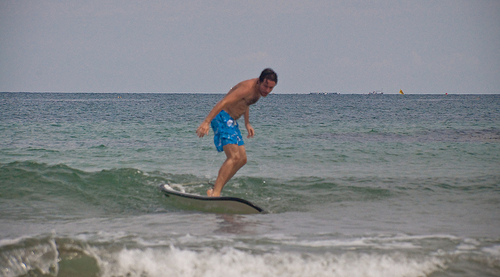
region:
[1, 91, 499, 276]
Blue ocean.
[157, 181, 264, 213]
Surfboard.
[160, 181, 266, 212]
White surfboard with black edging.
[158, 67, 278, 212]
Man on a surfboard.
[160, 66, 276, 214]
A surfer dude wearing blue shorts.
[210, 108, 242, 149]
Blue shorts with a floral print.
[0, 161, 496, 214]
An smooth ocean wave.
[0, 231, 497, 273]
Foamy ocean surf.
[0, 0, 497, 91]
A clear blue sky.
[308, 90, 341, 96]
A ship in the far distance.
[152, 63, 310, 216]
A man rides a surfboard.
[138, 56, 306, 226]
A man is surfing a wave.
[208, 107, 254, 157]
The man wears blue shorts.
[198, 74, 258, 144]
The man is shirtless.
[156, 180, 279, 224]
The bottom of the surfboard is visible.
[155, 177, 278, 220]
The surfboard is black and white.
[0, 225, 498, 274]
A wave is breaking in front of the man.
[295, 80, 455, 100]
Objects on the water can be seen.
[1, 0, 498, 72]
The sky is blue.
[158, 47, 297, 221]
The man is looking at the water.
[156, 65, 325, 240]
A young man surfing.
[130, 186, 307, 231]
a surfboard.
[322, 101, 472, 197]
The ocean waves.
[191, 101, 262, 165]
The man's blue swimtrunks.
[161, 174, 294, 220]
The man's feet on the board.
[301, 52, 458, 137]
The blue horizon line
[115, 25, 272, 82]
The light blue sky.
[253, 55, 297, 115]
The man's head and hair.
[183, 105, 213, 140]
The man's right hand.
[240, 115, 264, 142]
The man with the left hand.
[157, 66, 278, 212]
the man is surfing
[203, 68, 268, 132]
the man is shirtless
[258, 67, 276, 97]
the man has short hair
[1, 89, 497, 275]
the man is in the water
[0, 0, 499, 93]
the sky is blue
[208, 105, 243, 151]
the shorts are blue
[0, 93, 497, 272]
the water is green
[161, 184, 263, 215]
the surf board is black and white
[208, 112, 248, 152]
the shorts have a pattern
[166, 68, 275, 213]
the man is looking down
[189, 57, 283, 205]
man at the beach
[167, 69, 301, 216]
man surfing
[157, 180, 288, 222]
white surf board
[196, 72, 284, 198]
man wearing blue shorts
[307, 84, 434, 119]
small ships in the ocean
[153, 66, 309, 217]
man with blue swim shorts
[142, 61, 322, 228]
man surfing on the ocean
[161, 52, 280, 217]
shirtless man surfing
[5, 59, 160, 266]
waves in the ocean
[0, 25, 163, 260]
green ocean water